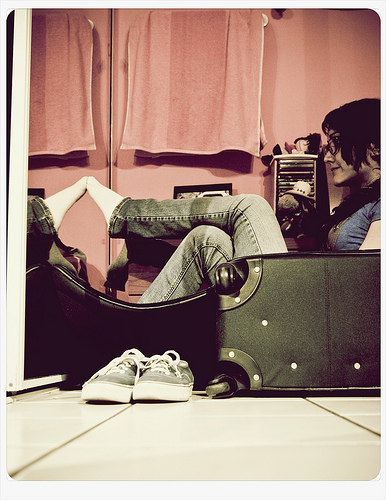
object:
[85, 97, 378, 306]
woman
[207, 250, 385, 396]
luggage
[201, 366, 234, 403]
wheel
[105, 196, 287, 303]
blue jeans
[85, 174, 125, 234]
sock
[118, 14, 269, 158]
towel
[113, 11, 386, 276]
wall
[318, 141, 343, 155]
glasses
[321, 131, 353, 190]
face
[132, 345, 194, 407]
sneakers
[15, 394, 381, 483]
ground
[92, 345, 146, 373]
laces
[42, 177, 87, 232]
foot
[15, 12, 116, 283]
mirror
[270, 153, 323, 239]
tower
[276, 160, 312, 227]
cds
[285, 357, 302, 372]
silver rivets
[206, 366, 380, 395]
bottom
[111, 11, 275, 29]
rack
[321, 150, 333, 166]
nose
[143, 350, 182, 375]
strings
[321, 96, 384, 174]
short hair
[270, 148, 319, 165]
book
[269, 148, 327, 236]
shelf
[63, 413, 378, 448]
tile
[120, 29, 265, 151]
window